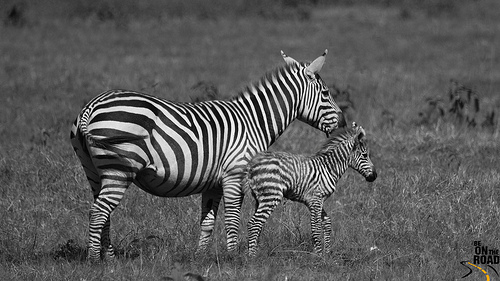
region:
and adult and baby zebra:
[67, 39, 384, 272]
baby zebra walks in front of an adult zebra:
[64, 47, 380, 262]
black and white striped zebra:
[62, 38, 349, 272]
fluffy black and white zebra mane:
[312, 122, 359, 160]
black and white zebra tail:
[69, 92, 151, 152]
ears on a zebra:
[278, 44, 330, 79]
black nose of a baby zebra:
[364, 164, 381, 183]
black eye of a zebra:
[317, 86, 332, 99]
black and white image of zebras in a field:
[2, 6, 498, 278]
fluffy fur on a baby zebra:
[237, 114, 379, 259]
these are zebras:
[30, 15, 487, 230]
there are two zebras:
[102, 54, 412, 241]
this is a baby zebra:
[193, 129, 415, 235]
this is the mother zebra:
[63, 75, 321, 160]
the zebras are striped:
[61, 42, 445, 256]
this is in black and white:
[45, 43, 475, 243]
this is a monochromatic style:
[12, 32, 453, 279]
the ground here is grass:
[362, 77, 486, 275]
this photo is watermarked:
[440, 236, 496, 271]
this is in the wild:
[43, 16, 448, 246]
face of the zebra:
[299, 43, 349, 136]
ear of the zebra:
[308, 50, 336, 77]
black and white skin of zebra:
[164, 99, 229, 137]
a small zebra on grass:
[261, 136, 413, 270]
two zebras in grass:
[43, 41, 430, 279]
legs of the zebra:
[63, 180, 156, 262]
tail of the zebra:
[71, 85, 119, 117]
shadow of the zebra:
[34, 230, 88, 267]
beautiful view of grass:
[40, 15, 481, 271]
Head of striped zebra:
[275, 47, 355, 137]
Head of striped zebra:
[335, 119, 385, 184]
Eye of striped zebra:
[318, 87, 333, 99]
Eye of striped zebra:
[356, 152, 372, 159]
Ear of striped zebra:
[272, 42, 302, 70]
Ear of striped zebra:
[307, 49, 334, 74]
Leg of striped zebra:
[85, 173, 132, 257]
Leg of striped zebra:
[222, 174, 245, 261]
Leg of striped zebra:
[240, 194, 281, 261]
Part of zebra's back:
[163, 107, 235, 141]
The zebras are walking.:
[63, 37, 396, 244]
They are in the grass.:
[43, 50, 395, 245]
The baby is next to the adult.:
[34, 51, 421, 268]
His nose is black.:
[363, 164, 383, 186]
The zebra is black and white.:
[61, 24, 398, 274]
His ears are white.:
[255, 44, 332, 74]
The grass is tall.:
[21, 26, 492, 276]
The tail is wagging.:
[59, 102, 155, 184]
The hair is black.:
[96, 130, 150, 150]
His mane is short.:
[233, 50, 316, 94]